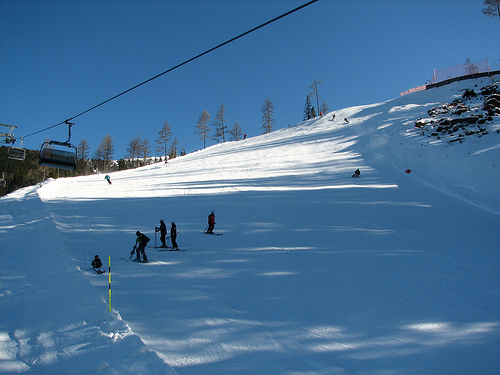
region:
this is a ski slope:
[86, 97, 299, 332]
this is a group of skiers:
[22, 189, 251, 319]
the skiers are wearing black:
[55, 162, 310, 334]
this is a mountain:
[355, 54, 489, 237]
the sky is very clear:
[137, 93, 171, 120]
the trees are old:
[92, 73, 250, 225]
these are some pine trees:
[157, 98, 252, 174]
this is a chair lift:
[32, 123, 98, 192]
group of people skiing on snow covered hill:
[71, 188, 246, 281]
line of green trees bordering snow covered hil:
[80, 91, 322, 178]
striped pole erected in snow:
[99, 254, 123, 321]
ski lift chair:
[29, 110, 94, 182]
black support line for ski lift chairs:
[1, 3, 306, 152]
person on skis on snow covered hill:
[191, 201, 229, 242]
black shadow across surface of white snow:
[8, 185, 455, 370]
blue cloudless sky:
[23, 16, 403, 114]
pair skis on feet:
[148, 240, 200, 257]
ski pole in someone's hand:
[149, 222, 162, 249]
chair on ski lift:
[38, 121, 79, 169]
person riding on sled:
[92, 253, 108, 275]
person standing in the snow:
[130, 228, 153, 264]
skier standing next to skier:
[152, 217, 170, 247]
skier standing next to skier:
[168, 220, 178, 250]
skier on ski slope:
[206, 210, 216, 235]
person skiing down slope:
[350, 167, 360, 177]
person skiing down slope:
[104, 175, 111, 185]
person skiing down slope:
[342, 117, 349, 125]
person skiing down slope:
[240, 132, 247, 140]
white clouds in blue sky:
[47, 25, 79, 40]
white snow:
[292, 246, 367, 310]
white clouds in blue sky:
[261, 42, 286, 59]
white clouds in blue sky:
[165, 19, 223, 61]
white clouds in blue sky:
[92, 42, 134, 87]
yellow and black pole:
[103, 253, 117, 315]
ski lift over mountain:
[36, 136, 81, 171]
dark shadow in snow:
[279, 130, 355, 139]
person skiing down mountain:
[103, 174, 112, 184]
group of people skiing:
[127, 210, 218, 262]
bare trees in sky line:
[194, 108, 211, 148]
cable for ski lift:
[69, 110, 86, 123]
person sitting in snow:
[87, 253, 107, 275]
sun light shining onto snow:
[415, 321, 442, 330]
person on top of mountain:
[239, 133, 249, 138]